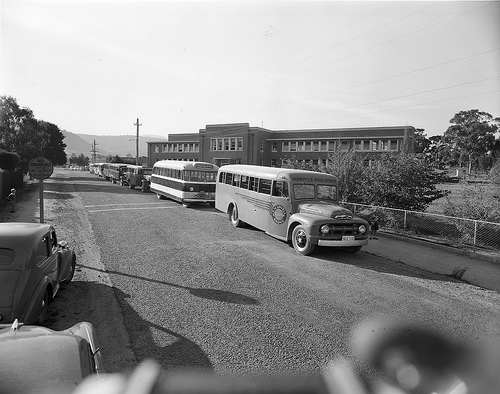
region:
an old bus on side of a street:
[208, 156, 378, 272]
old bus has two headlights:
[308, 215, 379, 242]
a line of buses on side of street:
[76, 144, 373, 259]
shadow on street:
[85, 255, 270, 320]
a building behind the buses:
[141, 116, 421, 166]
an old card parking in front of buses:
[1, 206, 91, 319]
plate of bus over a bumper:
[311, 231, 373, 248]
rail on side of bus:
[373, 200, 499, 252]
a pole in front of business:
[125, 106, 149, 161]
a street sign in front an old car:
[18, 146, 63, 216]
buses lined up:
[114, 107, 349, 326]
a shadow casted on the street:
[66, 211, 313, 346]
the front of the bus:
[299, 208, 391, 250]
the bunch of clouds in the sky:
[31, 71, 401, 121]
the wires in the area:
[174, 29, 465, 133]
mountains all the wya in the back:
[31, 88, 174, 173]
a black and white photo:
[9, 76, 465, 285]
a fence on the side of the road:
[429, 204, 486, 257]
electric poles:
[106, 106, 168, 191]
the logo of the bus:
[256, 191, 323, 248]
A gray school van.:
[215, 164, 371, 252]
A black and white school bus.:
[142, 157, 215, 204]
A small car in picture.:
[0, 214, 79, 321]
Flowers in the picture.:
[463, 183, 498, 228]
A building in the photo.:
[214, 118, 415, 162]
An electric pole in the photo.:
[128, 113, 146, 156]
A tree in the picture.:
[446, 104, 497, 171]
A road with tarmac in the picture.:
[141, 230, 253, 349]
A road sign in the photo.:
[25, 152, 59, 214]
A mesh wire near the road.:
[413, 209, 493, 249]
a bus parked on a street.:
[206, 149, 376, 262]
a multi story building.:
[142, 100, 439, 196]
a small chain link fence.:
[338, 182, 495, 251]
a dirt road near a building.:
[50, 161, 493, 364]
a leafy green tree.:
[0, 84, 92, 227]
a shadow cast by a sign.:
[75, 249, 283, 318]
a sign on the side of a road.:
[28, 133, 65, 225]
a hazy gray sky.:
[0, 3, 497, 137]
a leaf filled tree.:
[409, 87, 496, 184]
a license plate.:
[336, 227, 361, 246]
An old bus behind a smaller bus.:
[148, 154, 216, 210]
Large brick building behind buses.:
[145, 121, 432, 176]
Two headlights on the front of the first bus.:
[317, 222, 366, 236]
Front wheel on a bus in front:
[288, 222, 313, 254]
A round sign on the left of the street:
[28, 154, 53, 224]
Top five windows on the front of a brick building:
[209, 135, 244, 154]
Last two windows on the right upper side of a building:
[380, 138, 399, 153]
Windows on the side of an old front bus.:
[216, 169, 288, 199]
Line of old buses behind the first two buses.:
[86, 163, 153, 193]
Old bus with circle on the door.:
[210, 161, 372, 255]